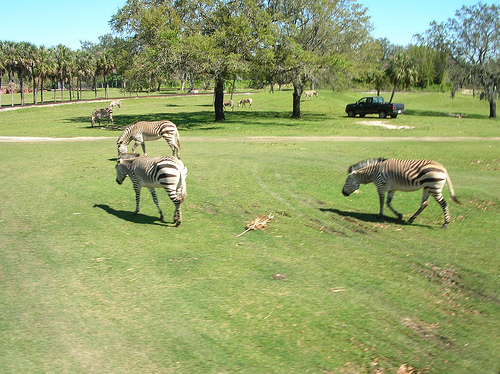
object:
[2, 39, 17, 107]
tree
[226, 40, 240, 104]
tree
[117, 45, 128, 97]
tree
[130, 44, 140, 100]
tree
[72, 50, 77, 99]
tree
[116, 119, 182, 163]
zebra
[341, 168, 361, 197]
head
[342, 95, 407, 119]
truck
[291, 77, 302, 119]
tree trunk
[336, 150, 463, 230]
zebra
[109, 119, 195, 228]
two zebras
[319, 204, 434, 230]
shadow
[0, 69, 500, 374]
field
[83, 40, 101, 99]
palm trees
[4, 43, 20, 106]
palm trees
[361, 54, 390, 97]
palm trees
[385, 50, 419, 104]
palm trees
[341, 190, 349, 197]
muzzle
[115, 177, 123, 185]
muzzle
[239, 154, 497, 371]
tire tracks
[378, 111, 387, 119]
wheel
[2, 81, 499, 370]
grass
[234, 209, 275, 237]
leaf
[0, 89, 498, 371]
ground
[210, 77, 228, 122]
trunks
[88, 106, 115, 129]
zebra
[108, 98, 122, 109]
zebra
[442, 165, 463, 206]
tail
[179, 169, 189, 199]
tail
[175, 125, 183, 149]
tail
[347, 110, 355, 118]
wheels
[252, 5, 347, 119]
tree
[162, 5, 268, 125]
tree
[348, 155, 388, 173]
mane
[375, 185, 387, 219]
legs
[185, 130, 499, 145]
path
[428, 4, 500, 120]
trees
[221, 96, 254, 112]
two zebras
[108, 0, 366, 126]
two trees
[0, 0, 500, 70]
sky